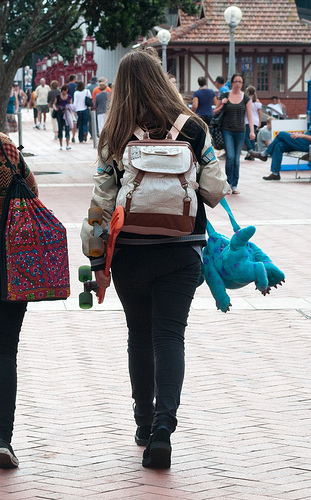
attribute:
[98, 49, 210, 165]
hair — brown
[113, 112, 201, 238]
backpack — brown, white, beige, multi-colored, tan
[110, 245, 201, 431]
pants — black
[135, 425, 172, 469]
shoes — black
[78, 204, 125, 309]
skateboard — red, green, orange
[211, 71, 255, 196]
woman — young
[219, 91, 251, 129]
tanktop — brown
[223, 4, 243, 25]
light — electric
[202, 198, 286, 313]
bag — blue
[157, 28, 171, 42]
sphere — glass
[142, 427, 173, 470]
shoe — black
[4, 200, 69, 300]
bag — pink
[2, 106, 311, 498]
walkway — brick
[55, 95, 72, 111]
shirt — black, white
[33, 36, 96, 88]
posts — red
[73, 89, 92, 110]
shirt — white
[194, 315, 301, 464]
bricks — red